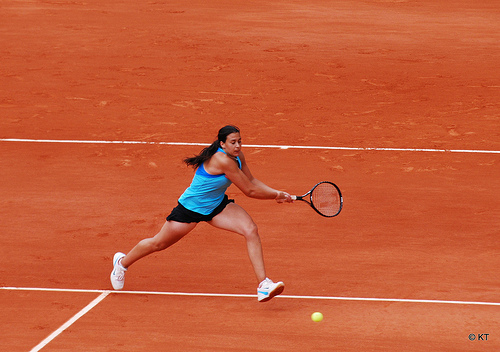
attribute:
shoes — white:
[113, 247, 128, 290]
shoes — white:
[256, 276, 283, 301]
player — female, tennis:
[102, 117, 289, 319]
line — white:
[1, 136, 498, 153]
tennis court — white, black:
[1, 0, 496, 350]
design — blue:
[257, 287, 268, 295]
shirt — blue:
[180, 149, 246, 230]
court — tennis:
[299, 103, 491, 345]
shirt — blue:
[176, 170, 306, 227]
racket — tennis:
[289, 179, 342, 218]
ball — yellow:
[304, 308, 329, 325]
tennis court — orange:
[6, 6, 498, 124]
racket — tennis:
[304, 175, 348, 224]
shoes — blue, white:
[250, 278, 285, 303]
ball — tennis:
[283, 278, 343, 350]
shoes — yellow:
[87, 229, 301, 337]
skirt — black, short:
[167, 194, 247, 232]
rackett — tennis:
[271, 166, 368, 233]